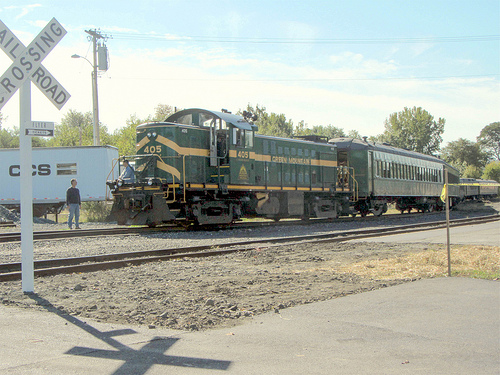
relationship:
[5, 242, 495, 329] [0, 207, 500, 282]
dirt next to tracks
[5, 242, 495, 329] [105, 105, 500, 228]
dirt next to green train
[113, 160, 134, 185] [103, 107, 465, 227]
driver sits on train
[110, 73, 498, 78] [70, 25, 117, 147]
wire coming off pole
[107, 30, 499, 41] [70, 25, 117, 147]
wire coming off pole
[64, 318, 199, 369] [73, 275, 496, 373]
shadow on ground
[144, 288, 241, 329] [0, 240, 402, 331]
rocks in dirt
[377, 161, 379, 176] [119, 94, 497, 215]
window on train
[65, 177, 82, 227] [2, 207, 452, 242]
man near tracks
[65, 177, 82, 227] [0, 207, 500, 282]
man near tracks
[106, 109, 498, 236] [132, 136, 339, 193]
green train has yellow stripes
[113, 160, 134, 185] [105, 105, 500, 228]
driver sitting on green train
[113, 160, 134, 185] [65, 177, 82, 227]
driver talking to man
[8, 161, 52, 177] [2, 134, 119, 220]
ccs painted on trailer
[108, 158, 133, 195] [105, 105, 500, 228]
driver sitting on green train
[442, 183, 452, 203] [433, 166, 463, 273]
flag hanging from stick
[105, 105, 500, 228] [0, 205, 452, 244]
green train stopped on tracks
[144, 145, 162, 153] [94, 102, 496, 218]
number painted on train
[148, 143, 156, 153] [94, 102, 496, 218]
number painted on train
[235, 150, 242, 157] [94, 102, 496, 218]
number painted on train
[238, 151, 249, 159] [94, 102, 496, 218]
number painted on train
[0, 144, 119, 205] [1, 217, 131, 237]
trailer parked on dirt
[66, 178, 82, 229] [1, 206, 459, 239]
man standing next to track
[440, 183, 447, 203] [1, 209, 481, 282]
flag posted next to track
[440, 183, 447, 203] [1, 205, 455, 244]
flag posted next to track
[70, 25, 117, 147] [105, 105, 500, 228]
pole standing behind green train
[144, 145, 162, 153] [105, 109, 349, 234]
number painted on train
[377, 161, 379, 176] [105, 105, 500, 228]
window built into green train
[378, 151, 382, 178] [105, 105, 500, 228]
window built into green train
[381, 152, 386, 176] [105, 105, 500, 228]
window built into green train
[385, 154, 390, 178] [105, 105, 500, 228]
window built into green train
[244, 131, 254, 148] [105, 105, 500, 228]
window built into green train